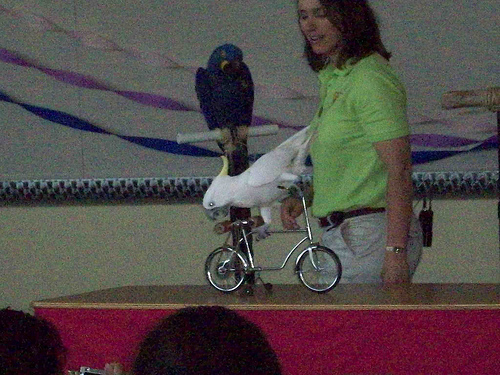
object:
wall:
[0, 1, 500, 316]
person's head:
[295, 0, 382, 57]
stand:
[32, 282, 497, 374]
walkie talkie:
[417, 187, 436, 250]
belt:
[306, 204, 391, 231]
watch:
[386, 244, 410, 255]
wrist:
[384, 240, 412, 259]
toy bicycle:
[202, 183, 349, 298]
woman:
[278, 0, 428, 286]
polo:
[306, 48, 420, 221]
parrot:
[191, 40, 267, 183]